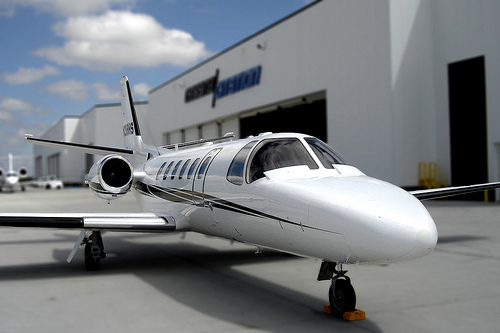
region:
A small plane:
[14, 71, 464, 327]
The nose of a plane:
[322, 172, 459, 268]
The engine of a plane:
[62, 150, 143, 204]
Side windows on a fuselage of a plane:
[152, 153, 214, 195]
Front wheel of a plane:
[308, 262, 368, 325]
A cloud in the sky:
[49, 9, 204, 70]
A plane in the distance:
[0, 150, 47, 194]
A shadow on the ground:
[123, 240, 265, 331]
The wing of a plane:
[0, 201, 185, 239]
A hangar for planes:
[152, 1, 497, 143]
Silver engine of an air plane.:
[88, 143, 140, 215]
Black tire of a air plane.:
[297, 271, 384, 323]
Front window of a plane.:
[214, 116, 359, 197]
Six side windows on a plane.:
[136, 150, 237, 194]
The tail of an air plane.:
[31, 83, 147, 162]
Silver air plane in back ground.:
[0, 147, 47, 199]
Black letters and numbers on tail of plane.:
[101, 112, 151, 144]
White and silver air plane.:
[32, 102, 424, 297]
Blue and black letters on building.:
[176, 81, 289, 112]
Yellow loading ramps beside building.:
[416, 140, 451, 198]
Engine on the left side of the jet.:
[81, 154, 133, 201]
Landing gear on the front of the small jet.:
[325, 262, 359, 317]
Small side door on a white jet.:
[190, 146, 222, 206]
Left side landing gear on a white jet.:
[81, 234, 108, 272]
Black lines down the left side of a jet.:
[134, 177, 345, 235]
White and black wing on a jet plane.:
[0, 211, 196, 234]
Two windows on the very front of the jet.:
[243, 134, 348, 184]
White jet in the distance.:
[0, 151, 50, 194]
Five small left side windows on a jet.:
[152, 156, 199, 180]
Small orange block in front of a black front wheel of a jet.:
[341, 309, 367, 320]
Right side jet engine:
[84, 154, 135, 196]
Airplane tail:
[120, 75, 152, 146]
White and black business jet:
[25, 77, 439, 311]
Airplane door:
[195, 146, 222, 197]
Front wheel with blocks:
[323, 275, 367, 327]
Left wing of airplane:
[1, 210, 179, 240]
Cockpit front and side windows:
[230, 137, 364, 185]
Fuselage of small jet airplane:
[138, 144, 444, 267]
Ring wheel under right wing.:
[83, 232, 109, 268]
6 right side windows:
[151, 155, 218, 180]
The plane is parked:
[16, 99, 427, 328]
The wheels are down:
[57, 226, 433, 331]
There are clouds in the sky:
[17, 15, 314, 140]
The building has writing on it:
[158, 62, 345, 147]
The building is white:
[318, 34, 418, 154]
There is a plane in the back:
[1, 143, 91, 220]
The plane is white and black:
[191, 144, 418, 264]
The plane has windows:
[137, 151, 358, 216]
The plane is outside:
[15, 120, 496, 293]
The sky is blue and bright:
[45, 22, 257, 134]